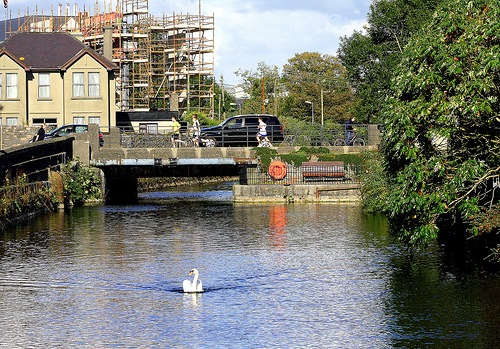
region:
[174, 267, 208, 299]
a pure white swan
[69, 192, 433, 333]
a calm water way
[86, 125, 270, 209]
a bridge over the water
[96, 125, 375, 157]
a simple metal fence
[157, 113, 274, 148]
some kids running over a bridge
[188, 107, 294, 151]
a black suv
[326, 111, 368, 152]
a boy on a bike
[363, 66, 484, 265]
a tree overhanging the water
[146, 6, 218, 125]
some scaffolding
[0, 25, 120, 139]
a tan building with a black roof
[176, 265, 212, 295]
the goose is in the water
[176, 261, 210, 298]
the goose is white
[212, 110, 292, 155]
the truck is black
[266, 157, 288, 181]
life jacket is on the wall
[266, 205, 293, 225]
reflection is in the water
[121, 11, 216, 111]
the building is under construction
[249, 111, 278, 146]
the man is running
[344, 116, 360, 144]
the man is on the bike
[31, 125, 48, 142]
the shirt is black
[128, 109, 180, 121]
the roof top is black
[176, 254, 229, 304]
white duck in the water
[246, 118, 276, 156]
person running on the bridge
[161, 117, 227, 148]
two people running on the bridge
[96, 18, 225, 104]
construction of a building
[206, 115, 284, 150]
black van driving on the road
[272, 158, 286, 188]
orange life preserve on wall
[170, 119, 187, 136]
yellow shirt on runner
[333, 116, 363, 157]
person on a bicycle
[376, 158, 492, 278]
leaves hanging over into water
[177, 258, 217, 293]
swan on the water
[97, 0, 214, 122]
a building under construction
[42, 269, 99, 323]
the water is calm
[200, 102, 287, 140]
man walking next to car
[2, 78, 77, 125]
windows on the building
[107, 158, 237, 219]
water under the bridge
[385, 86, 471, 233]
leaves on the tree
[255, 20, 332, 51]
large clouds in sky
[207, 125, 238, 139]
the car is black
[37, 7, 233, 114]
the scaffolding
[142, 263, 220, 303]
the swan on the water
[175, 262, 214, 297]
the swan is swimming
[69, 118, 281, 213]
bridge over the water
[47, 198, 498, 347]
the water is calm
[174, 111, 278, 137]
people on the bridge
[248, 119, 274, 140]
the person is running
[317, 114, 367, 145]
the person riding bicycle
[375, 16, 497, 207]
the trees with green leaves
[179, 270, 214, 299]
the swan is white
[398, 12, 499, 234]
A tree in a city.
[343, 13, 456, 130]
A tree in a city.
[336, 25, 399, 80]
A tree in a city.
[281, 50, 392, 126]
A tree in a city.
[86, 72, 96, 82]
glass window on the building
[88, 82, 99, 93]
glass window on the building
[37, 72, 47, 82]
glass window on the building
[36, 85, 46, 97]
glass window on the building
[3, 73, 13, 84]
glass window on the building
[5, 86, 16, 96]
glass window on the building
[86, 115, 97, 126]
glass window on the building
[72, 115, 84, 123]
glass window on the building